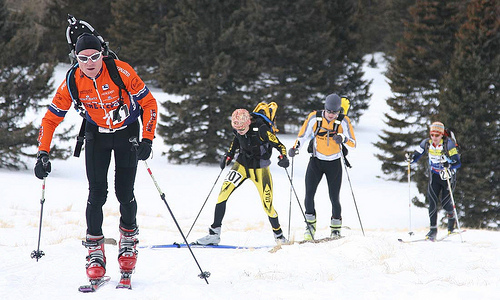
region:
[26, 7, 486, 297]
The people are up in the mountains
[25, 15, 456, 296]
The people are at a ski resort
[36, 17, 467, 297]
The people are on their vacation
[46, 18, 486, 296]
The people are doing some snow skiing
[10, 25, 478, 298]
The people are all holding ski poles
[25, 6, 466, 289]
The people are all wearing warm clothes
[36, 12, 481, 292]
The people are all using snow skis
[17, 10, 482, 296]
The people are out in the daytime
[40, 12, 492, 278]
The people are enjoying winter sports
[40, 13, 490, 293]
The people are getting some exercise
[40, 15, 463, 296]
The people are all wearing hats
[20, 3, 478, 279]
The people are wearing warm clothing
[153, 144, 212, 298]
left ski pole in hand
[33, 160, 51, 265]
right ski pole on ground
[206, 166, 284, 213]
yellow pants worn by skiier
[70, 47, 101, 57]
goggles on man's face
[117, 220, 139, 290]
red ski boot on ground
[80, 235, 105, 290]
left red ski boot on ground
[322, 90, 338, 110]
hat on the man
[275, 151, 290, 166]
left hand of the woman skiing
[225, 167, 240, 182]
number on the skiiers' pants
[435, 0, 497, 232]
tree on the ground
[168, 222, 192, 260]
There is a long ski pole visible here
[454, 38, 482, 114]
There is a dark green tree in the distance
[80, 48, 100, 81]
This man is wearing white sunglasses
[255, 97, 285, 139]
This man has yellow snowshoes in his backpack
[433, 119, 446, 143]
This person is wearing a multi-colored hat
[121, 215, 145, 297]
This person is wearing red ski boots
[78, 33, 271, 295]
Jackson Mingus took this photo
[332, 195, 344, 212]
This person is wearing black pants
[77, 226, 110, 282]
bright colored ski boot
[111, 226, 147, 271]
bright colored ski boot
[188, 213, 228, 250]
bright colored ski boot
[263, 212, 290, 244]
bright colored ski boot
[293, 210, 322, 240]
bright colored ski boot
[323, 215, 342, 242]
bright colored ski boot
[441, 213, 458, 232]
bright colored ski boot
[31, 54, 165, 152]
bright colored ski shirt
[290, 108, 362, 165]
bright colored ski shirt